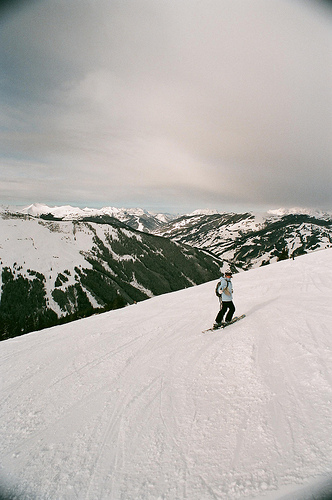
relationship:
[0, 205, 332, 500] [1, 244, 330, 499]
snow on ground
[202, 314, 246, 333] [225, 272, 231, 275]
skis has glasses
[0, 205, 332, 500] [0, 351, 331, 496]
snow has ground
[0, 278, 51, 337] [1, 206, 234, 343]
trees on mountain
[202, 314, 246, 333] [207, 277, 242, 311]
skis wearing jacket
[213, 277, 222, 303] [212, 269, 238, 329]
backpack on person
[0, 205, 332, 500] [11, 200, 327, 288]
snow cover mountains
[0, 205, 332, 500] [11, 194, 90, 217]
snow capped mountaintop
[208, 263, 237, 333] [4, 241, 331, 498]
person on slope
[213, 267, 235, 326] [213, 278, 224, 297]
person carrying a backpack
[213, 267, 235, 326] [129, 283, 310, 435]
person standing upright in snow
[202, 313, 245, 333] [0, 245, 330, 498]
skis on ice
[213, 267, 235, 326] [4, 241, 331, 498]
person on slope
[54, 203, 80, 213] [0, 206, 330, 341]
snow capped mountains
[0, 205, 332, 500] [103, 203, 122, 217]
snow capped mountaintop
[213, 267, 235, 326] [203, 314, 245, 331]
person wearing skis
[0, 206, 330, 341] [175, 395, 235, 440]
mountains covered with snow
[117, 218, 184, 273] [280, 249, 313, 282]
ground covered with snow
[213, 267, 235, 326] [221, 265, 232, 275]
person wearing helmet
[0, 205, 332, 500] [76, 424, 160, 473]
snow on ground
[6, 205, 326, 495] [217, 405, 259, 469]
snow on ground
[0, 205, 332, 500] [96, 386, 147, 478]
snow on ground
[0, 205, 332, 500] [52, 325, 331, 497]
snow on ground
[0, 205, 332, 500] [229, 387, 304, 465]
snow on ground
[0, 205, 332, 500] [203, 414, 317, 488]
snow on ground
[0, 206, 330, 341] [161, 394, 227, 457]
mountains over snow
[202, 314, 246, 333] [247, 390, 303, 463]
skis in snow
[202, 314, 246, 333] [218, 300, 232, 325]
skis wearing pants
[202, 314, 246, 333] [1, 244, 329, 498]
skis rolling on mountain